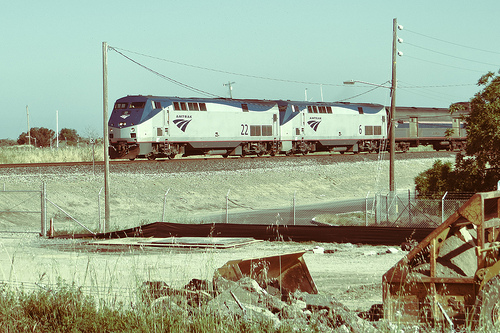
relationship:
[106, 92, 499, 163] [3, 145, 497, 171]
train on tracks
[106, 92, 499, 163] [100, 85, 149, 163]
train has front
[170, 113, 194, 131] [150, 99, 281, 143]
logo on side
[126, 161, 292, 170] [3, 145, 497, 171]
rocks on tracks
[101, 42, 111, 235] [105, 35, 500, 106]
pole has line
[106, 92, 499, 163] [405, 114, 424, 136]
train has compartment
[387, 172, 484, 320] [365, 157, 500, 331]
front end of bulldozer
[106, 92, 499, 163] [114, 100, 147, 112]
train has windshield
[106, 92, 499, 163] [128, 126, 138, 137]
train has headlight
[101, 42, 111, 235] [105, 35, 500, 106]
pole has wires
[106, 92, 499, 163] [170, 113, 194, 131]
train has logo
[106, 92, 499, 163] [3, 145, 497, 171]
train on top of tracks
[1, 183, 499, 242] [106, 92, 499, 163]
fence near train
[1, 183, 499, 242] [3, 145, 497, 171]
fence near tracks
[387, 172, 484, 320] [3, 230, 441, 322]
dumpster on road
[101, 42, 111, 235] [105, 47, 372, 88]
pole has line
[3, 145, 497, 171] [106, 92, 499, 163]
tracks near train